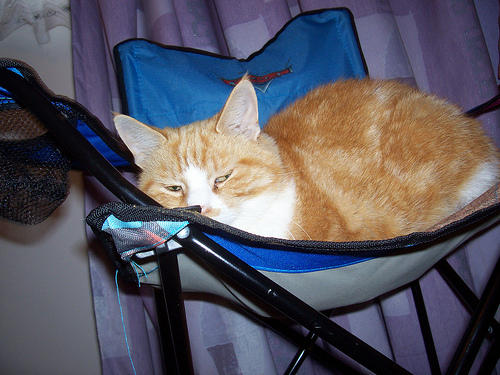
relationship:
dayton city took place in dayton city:
[2, 3, 492, 361] [2, 3, 492, 361]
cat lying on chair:
[104, 80, 496, 259] [83, 40, 430, 362]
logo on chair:
[222, 54, 314, 98] [107, 28, 468, 340]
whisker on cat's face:
[226, 190, 288, 223] [113, 98, 257, 212]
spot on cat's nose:
[178, 148, 212, 213] [165, 169, 218, 226]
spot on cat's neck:
[249, 188, 291, 221] [110, 81, 494, 225]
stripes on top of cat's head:
[167, 117, 207, 177] [102, 92, 316, 250]